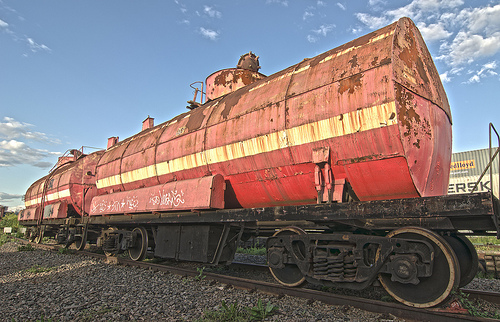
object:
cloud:
[196, 25, 221, 42]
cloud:
[313, 21, 335, 38]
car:
[7, 140, 112, 246]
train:
[0, 15, 483, 322]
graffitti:
[144, 185, 185, 209]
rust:
[378, 84, 424, 145]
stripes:
[88, 96, 423, 189]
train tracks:
[0, 227, 499, 322]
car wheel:
[259, 225, 313, 292]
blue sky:
[0, 4, 172, 130]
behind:
[452, 143, 499, 195]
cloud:
[182, 5, 219, 41]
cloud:
[3, 116, 71, 171]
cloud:
[2, 6, 53, 56]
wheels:
[366, 222, 460, 313]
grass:
[203, 299, 279, 319]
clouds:
[16, 60, 49, 89]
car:
[90, 16, 486, 310]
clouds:
[0, 116, 62, 172]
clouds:
[173, 0, 222, 42]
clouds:
[0, 0, 55, 62]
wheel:
[92, 224, 123, 253]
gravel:
[16, 257, 27, 263]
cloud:
[352, 1, 500, 89]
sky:
[4, 0, 484, 178]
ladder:
[39, 176, 59, 225]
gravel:
[183, 283, 195, 293]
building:
[448, 139, 497, 200]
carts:
[8, 14, 497, 321]